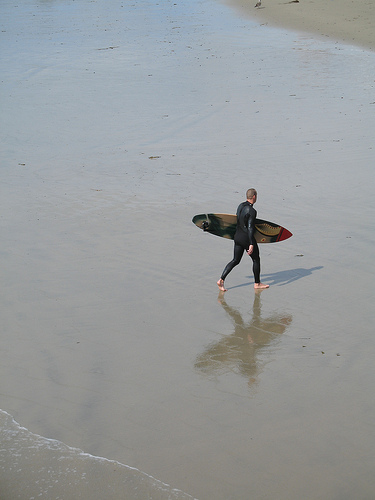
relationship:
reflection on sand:
[196, 282, 296, 401] [46, 81, 366, 475]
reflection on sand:
[196, 282, 296, 401] [44, 67, 374, 498]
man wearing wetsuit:
[216, 188, 270, 293] [214, 184, 273, 301]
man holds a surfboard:
[216, 188, 270, 293] [189, 203, 313, 247]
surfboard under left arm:
[186, 212, 299, 248] [231, 202, 245, 224]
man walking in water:
[216, 188, 270, 293] [31, 68, 372, 483]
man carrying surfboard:
[216, 188, 270, 293] [184, 205, 295, 251]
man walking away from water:
[216, 188, 270, 293] [31, 68, 372, 483]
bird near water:
[253, 1, 262, 9] [192, 5, 363, 126]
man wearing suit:
[219, 187, 271, 292] [222, 200, 264, 283]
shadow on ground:
[231, 264, 322, 288] [44, 234, 363, 458]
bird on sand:
[248, 2, 265, 12] [14, 13, 363, 481]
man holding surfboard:
[216, 188, 270, 293] [188, 199, 299, 251]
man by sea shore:
[216, 188, 270, 293] [0, 0, 367, 496]